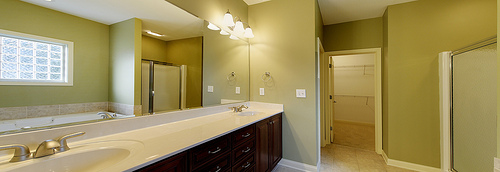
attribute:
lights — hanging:
[205, 11, 253, 46]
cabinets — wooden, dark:
[140, 111, 301, 171]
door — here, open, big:
[322, 42, 382, 157]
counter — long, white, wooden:
[1, 98, 281, 171]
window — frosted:
[3, 32, 80, 88]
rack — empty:
[262, 72, 279, 92]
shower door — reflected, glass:
[141, 58, 189, 112]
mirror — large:
[145, 54, 195, 113]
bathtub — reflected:
[0, 104, 124, 140]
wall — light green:
[252, 1, 312, 158]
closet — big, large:
[334, 43, 378, 152]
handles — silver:
[3, 124, 86, 157]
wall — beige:
[126, 28, 211, 119]